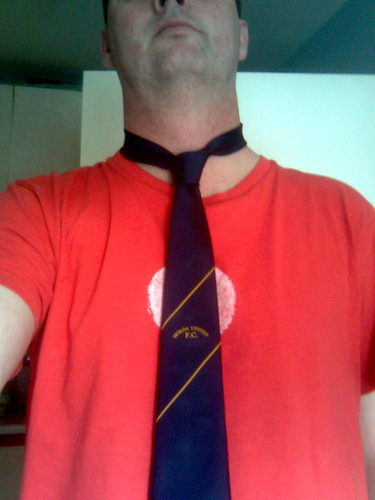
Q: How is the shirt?
A: Red.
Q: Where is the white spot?
A: Shirt.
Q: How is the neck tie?
A: On neck.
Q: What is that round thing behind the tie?
A: Its a white spot on the shirt.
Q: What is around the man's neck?
A: It's a dark neck tie.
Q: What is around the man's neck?
A: Its a tie.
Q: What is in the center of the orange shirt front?
A: Its a white circle.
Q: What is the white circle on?
A: Its a red shirt.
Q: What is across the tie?
A: They are gold stripes.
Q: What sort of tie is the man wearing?
A: It is a Blue tie with gold designs.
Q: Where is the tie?
A: It is around the neck of the man.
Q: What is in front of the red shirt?
A: It is a purple tie.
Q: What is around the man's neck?
A: A tie.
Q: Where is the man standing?
A: A room.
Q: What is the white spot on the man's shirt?
A: A design.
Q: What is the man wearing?
A: A shirt.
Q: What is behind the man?
A: A wall.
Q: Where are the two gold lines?
A: THE TIE.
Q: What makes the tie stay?
A: The knot.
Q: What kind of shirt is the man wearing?
A: A t shirt.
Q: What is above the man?
A: The ceiling.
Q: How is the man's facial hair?
A: No facial hair.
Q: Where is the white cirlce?
A: Under the tie.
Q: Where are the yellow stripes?
A: On the tie.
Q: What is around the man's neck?
A: A tie.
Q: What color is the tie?
A: Blue.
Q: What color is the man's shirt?
A: Red.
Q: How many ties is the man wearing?
A: One.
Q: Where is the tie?
A: On the man.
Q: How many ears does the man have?
A: Two.